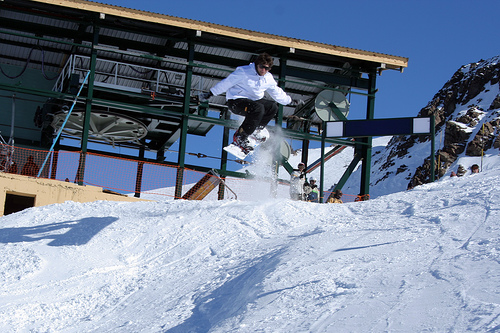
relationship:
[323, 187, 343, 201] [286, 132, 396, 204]
person on hill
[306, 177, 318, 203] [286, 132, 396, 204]
people on hill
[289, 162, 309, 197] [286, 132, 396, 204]
person on hill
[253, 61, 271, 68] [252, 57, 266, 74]
goggles on face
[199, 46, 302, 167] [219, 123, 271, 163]
person jumping on snowboard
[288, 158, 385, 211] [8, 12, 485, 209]
people in background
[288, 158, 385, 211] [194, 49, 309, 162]
people watching snowboarder